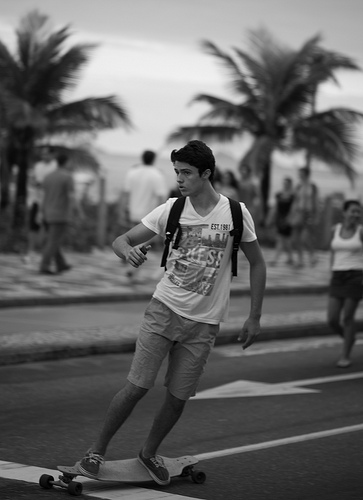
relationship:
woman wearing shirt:
[321, 188, 359, 409] [330, 222, 351, 271]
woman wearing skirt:
[329, 200, 359, 378] [329, 267, 350, 300]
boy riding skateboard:
[67, 137, 275, 494] [56, 461, 200, 482]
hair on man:
[165, 140, 215, 183] [74, 142, 276, 485]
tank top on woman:
[325, 222, 360, 274] [325, 198, 362, 367]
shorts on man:
[137, 296, 219, 401] [74, 142, 276, 485]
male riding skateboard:
[79, 139, 267, 486] [51, 424, 252, 490]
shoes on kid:
[72, 443, 170, 485] [74, 137, 268, 487]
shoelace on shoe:
[82, 448, 105, 466] [66, 442, 198, 483]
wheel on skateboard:
[191, 469, 207, 482] [83, 447, 191, 482]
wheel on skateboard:
[65, 480, 84, 497] [83, 447, 191, 482]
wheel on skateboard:
[41, 471, 54, 490] [83, 447, 191, 482]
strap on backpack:
[167, 203, 196, 241] [137, 192, 283, 256]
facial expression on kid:
[171, 159, 203, 200] [74, 137, 268, 487]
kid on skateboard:
[74, 137, 268, 487] [34, 452, 211, 498]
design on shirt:
[174, 224, 221, 304] [141, 192, 257, 324]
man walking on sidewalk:
[33, 147, 77, 274] [0, 241, 331, 308]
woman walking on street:
[325, 198, 362, 367] [0, 331, 361, 498]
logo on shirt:
[177, 246, 224, 265] [141, 192, 257, 324]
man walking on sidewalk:
[36, 153, 81, 277] [2, 244, 358, 297]